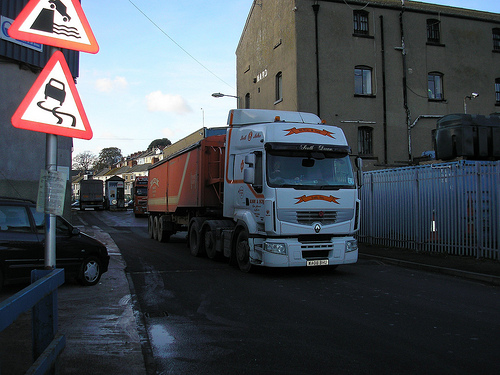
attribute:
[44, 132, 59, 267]
post — silver, metal, sign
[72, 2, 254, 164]
sky — clear, blue, cloudless